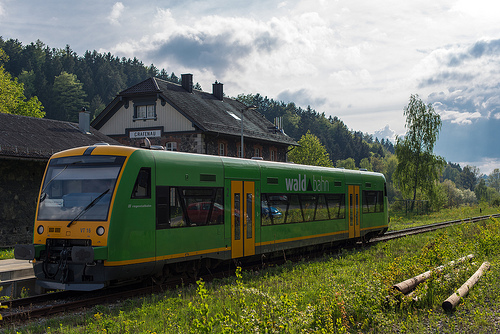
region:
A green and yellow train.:
[10, 142, 390, 297]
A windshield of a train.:
[35, 157, 121, 222]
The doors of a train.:
[230, 176, 255, 251]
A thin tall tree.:
[397, 90, 439, 216]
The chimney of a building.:
[176, 69, 197, 90]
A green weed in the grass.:
[231, 261, 246, 306]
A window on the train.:
[153, 186, 223, 227]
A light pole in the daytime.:
[236, 101, 260, 157]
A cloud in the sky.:
[273, 81, 332, 110]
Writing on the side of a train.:
[278, 170, 335, 194]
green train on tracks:
[5, 110, 422, 305]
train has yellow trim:
[20, 127, 141, 268]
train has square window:
[32, 136, 132, 243]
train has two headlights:
[35, 214, 118, 241]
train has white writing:
[280, 167, 338, 196]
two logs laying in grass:
[391, 236, 495, 320]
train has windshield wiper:
[52, 184, 111, 233]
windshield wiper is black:
[58, 188, 112, 226]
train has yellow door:
[216, 166, 269, 269]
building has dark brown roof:
[91, 48, 294, 164]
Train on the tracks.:
[31, 141, 393, 288]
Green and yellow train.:
[31, 147, 396, 300]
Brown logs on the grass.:
[390, 250, 491, 312]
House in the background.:
[96, 70, 298, 161]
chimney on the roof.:
[178, 67, 196, 93]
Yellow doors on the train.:
[229, 178, 257, 255]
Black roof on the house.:
[155, 76, 294, 146]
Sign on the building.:
[127, 124, 165, 139]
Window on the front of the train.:
[36, 150, 128, 232]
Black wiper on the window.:
[66, 188, 110, 230]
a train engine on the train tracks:
[31, 137, 391, 309]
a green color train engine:
[32, 142, 389, 297]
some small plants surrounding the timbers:
[381, 236, 493, 316]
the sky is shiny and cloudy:
[140, 2, 492, 62]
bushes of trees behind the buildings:
[3, 10, 284, 145]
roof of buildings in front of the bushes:
[0, 40, 300, 142]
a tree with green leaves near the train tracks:
[389, 95, 473, 233]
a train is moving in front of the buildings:
[1, 70, 391, 305]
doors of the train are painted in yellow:
[34, 148, 387, 290]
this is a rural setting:
[19, 13, 473, 312]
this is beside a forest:
[52, 25, 422, 328]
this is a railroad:
[18, 118, 481, 285]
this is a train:
[23, 111, 433, 271]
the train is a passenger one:
[17, 124, 411, 274]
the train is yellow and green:
[7, 118, 487, 244]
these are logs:
[391, 235, 493, 323]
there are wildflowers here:
[185, 268, 363, 330]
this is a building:
[46, 60, 416, 196]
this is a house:
[71, 73, 300, 176]